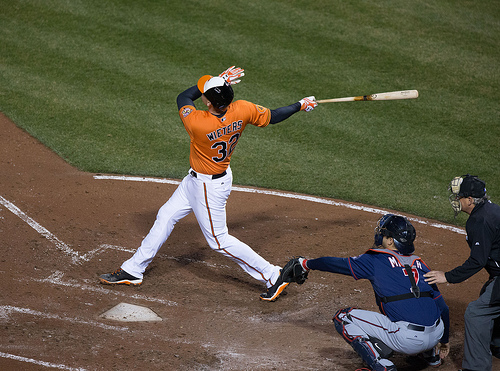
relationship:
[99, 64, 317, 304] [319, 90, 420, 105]
ballplayer has a bat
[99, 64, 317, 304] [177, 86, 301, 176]
ballplayer has a shirt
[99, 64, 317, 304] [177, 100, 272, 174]
ballplayer has on a jersey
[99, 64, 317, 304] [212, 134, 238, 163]
ballplayer number 32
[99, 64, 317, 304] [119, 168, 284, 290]
ballplayer has on pants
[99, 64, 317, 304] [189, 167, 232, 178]
ballplayer has on a belt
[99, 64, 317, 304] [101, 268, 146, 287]
ballplayer has on shoes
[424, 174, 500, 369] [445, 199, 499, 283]
umpire has on a shirt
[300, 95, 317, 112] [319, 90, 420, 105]
hand has a bat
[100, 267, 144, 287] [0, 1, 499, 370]
foot on ground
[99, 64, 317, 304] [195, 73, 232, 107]
ballplayer has a hat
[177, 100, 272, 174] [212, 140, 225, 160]
jersey has number 3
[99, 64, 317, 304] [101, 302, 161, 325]
ballplayer at home base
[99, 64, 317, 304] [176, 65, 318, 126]
ballplayer has arms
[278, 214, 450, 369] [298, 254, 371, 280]
catcher has an arm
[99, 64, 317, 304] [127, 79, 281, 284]
ballplayer has on a uniform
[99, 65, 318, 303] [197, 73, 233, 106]
ballplayer wearing a cap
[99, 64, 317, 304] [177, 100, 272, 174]
ballplayer wearing an jersey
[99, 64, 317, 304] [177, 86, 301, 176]
ballplayer wearing shirt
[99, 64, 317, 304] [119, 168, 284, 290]
ballplayer wearing pants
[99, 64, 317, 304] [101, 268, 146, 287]
ballplayer wearing shoes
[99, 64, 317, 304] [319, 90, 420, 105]
ballplayer swinging a bat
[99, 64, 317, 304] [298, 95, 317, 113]
ballplayer wearing gloves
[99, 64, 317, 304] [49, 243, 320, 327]
ballplayer in batters box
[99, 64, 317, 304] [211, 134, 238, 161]
ballplayer number 33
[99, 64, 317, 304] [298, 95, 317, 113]
ballplayer has on gloves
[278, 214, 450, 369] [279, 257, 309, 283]
catcher has on a mitt